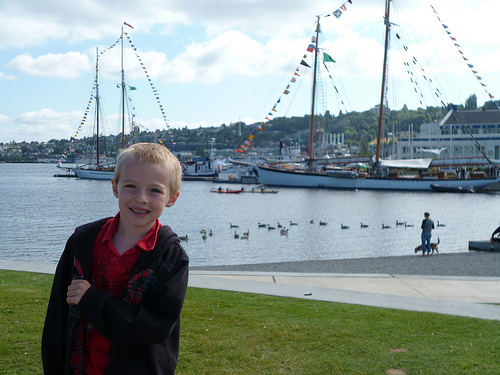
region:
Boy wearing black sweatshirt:
[61, 156, 191, 353]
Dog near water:
[413, 240, 439, 259]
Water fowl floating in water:
[226, 208, 348, 245]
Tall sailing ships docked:
[279, 48, 491, 197]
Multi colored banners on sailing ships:
[238, 27, 305, 157]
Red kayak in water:
[208, 184, 242, 205]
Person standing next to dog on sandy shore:
[398, 212, 448, 268]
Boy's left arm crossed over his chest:
[50, 231, 202, 333]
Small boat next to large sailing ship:
[428, 178, 480, 199]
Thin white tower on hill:
[230, 113, 248, 139]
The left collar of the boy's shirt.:
[102, 217, 118, 242]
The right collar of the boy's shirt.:
[137, 220, 168, 258]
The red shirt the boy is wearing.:
[87, 225, 131, 367]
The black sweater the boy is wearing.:
[65, 215, 190, 368]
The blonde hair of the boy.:
[109, 136, 194, 191]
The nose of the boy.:
[134, 191, 154, 202]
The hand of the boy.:
[58, 265, 89, 307]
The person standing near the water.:
[414, 212, 439, 250]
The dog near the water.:
[409, 227, 454, 257]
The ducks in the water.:
[154, 206, 464, 243]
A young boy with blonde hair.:
[29, 130, 200, 371]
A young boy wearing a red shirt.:
[43, 147, 202, 367]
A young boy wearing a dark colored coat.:
[30, 135, 195, 370]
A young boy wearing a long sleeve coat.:
[35, 133, 193, 369]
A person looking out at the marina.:
[401, 207, 447, 257]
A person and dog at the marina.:
[402, 202, 444, 258]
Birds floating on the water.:
[183, 209, 448, 251]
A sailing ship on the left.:
[59, 20, 224, 180]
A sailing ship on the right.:
[219, 5, 497, 197]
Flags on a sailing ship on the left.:
[61, 26, 189, 168]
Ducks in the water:
[253, 216, 350, 243]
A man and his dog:
[412, 207, 444, 262]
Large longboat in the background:
[242, 158, 498, 198]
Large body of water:
[11, 171, 57, 241]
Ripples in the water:
[13, 171, 50, 254]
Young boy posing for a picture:
[40, 138, 191, 373]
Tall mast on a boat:
[372, 2, 395, 177]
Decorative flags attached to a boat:
[221, 31, 311, 158]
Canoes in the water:
[207, 181, 284, 202]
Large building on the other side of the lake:
[396, 103, 498, 165]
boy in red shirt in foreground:
[40, 143, 188, 373]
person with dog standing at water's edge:
[413, 211, 440, 257]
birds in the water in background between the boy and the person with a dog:
[185, 215, 416, 244]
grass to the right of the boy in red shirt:
[184, 294, 497, 374]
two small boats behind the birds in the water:
[209, 185, 281, 195]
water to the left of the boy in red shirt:
[3, 165, 66, 254]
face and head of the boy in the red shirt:
[110, 141, 182, 228]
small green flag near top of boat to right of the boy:
[324, 50, 336, 65]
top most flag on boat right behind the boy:
[119, 19, 134, 33]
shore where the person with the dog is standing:
[285, 254, 497, 274]